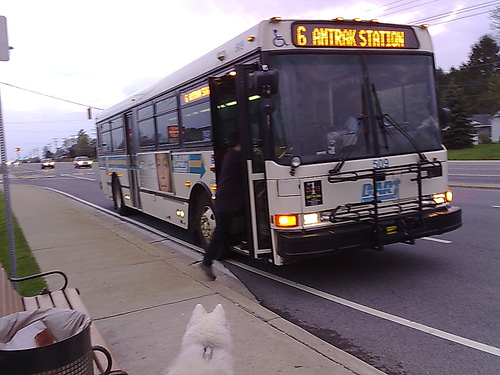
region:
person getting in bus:
[161, 126, 266, 284]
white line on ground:
[330, 289, 422, 349]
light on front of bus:
[281, 193, 338, 243]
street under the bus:
[376, 245, 465, 312]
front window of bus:
[270, 48, 450, 168]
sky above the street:
[41, 13, 154, 68]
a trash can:
[0, 306, 94, 373]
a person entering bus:
[195, 131, 250, 282]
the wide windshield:
[269, 50, 444, 156]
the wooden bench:
[1, 262, 125, 374]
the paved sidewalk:
[1, 180, 384, 373]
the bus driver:
[351, 94, 417, 148]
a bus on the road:
[88, 10, 463, 272]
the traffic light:
[83, 103, 95, 120]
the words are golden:
[307, 27, 404, 46]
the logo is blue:
[363, 177, 404, 204]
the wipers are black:
[316, 102, 431, 165]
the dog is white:
[181, 303, 237, 373]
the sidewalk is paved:
[55, 195, 144, 355]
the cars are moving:
[15, 150, 97, 175]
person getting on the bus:
[205, 139, 268, 280]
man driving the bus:
[345, 94, 402, 139]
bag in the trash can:
[10, 310, 89, 366]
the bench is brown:
[5, 273, 92, 361]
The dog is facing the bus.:
[172, 300, 232, 372]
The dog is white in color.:
[173, 301, 233, 373]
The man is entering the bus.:
[200, 137, 251, 282]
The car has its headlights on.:
[73, 154, 93, 169]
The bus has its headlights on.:
[273, 189, 457, 229]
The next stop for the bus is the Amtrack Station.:
[286, 18, 425, 56]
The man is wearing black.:
[201, 139, 255, 285]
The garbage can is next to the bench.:
[1, 306, 94, 374]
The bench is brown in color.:
[1, 270, 123, 373]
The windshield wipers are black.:
[326, 81, 442, 180]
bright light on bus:
[174, 75, 218, 113]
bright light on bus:
[328, 15, 362, 57]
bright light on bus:
[357, 15, 381, 49]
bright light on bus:
[300, 198, 322, 229]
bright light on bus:
[428, 176, 460, 214]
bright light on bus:
[164, 191, 181, 232]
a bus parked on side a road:
[68, 11, 475, 286]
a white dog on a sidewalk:
[153, 291, 250, 373]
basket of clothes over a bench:
[0, 265, 111, 371]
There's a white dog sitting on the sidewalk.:
[146, 288, 253, 369]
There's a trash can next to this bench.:
[5, 227, 107, 365]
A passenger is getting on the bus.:
[204, 28, 344, 303]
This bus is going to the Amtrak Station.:
[267, 12, 444, 284]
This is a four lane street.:
[459, 146, 487, 324]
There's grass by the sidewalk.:
[4, 169, 111, 297]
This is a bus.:
[86, 11, 438, 266]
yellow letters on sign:
[288, 18, 428, 54]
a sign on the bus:
[296, 19, 423, 53]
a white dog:
[175, 298, 253, 373]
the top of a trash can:
[0, 281, 114, 365]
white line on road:
[348, 297, 468, 343]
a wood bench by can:
[0, 223, 111, 373]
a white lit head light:
[297, 203, 338, 232]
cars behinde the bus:
[26, 128, 96, 186]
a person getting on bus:
[183, 120, 259, 293]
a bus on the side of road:
[66, 15, 458, 296]